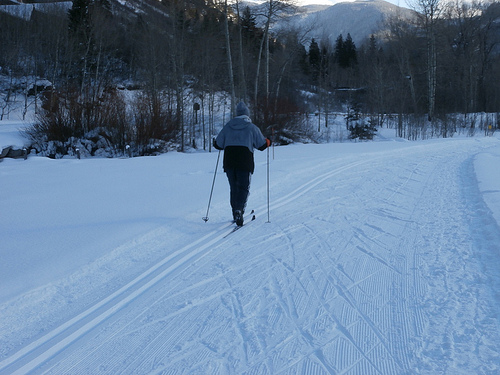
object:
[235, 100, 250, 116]
hat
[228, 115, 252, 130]
hood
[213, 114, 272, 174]
jacket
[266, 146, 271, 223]
stick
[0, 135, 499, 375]
tracks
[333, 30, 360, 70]
leaves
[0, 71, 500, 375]
snow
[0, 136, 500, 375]
floor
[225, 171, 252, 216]
pants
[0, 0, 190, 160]
tree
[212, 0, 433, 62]
mountain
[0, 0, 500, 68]
distance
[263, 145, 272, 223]
long/thin ski-pole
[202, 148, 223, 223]
long/thin ski-pole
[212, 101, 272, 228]
man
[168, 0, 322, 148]
trees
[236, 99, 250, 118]
head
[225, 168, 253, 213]
pant.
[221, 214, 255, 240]
ski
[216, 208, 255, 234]
ski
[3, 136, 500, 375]
ground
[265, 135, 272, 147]
hand